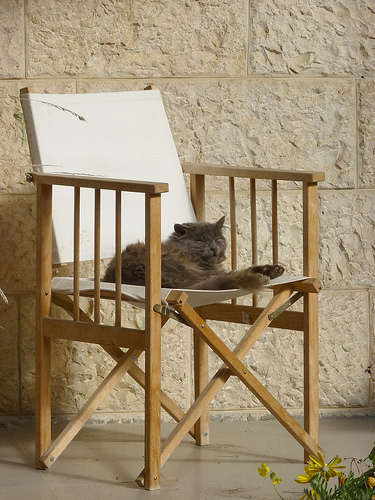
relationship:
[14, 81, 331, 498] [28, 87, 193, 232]
chair has cloth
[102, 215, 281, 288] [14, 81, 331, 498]
cat on chair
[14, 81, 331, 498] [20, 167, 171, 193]
chair has arm rest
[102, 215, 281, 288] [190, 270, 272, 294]
cat has tail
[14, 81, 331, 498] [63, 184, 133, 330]
chair has spindles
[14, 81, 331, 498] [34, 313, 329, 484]
chair has legs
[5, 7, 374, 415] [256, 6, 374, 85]
wall has stone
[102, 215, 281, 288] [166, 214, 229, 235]
cat has ears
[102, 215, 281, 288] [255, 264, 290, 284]
cat has paws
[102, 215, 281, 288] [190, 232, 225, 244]
cat has eyes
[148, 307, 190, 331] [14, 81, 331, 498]
hinge on chair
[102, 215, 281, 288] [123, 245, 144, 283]
cat has fur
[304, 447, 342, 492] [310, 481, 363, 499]
flower has leaves